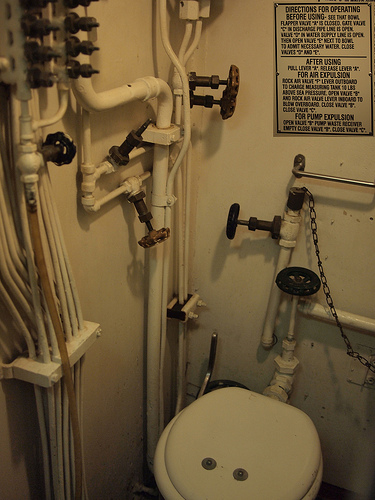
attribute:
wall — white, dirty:
[207, 33, 260, 60]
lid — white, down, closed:
[182, 427, 279, 473]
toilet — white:
[102, 436, 172, 491]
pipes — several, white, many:
[262, 259, 295, 391]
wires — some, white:
[316, 218, 337, 243]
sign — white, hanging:
[251, 0, 367, 142]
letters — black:
[277, 27, 323, 91]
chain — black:
[288, 207, 328, 297]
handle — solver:
[182, 322, 230, 390]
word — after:
[300, 56, 329, 66]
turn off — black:
[288, 187, 311, 216]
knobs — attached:
[117, 181, 169, 245]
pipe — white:
[135, 180, 181, 260]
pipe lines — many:
[126, 194, 175, 308]